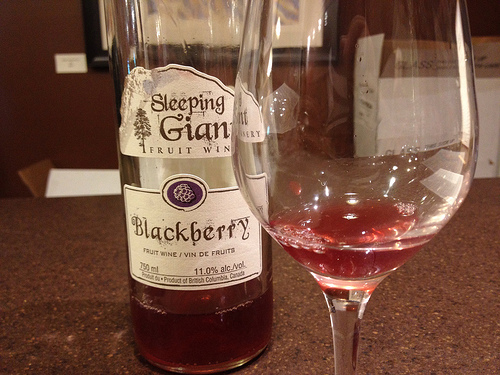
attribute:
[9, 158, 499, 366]
counter top — is marble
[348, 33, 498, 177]
box — white